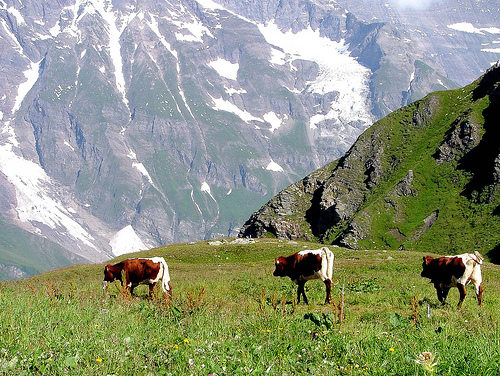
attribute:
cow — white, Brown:
[271, 241, 335, 302]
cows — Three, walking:
[84, 226, 484, 330]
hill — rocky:
[313, 121, 477, 231]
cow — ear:
[96, 243, 190, 303]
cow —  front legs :
[287, 281, 318, 309]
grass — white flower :
[96, 319, 374, 366]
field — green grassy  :
[30, 312, 302, 372]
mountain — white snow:
[6, 2, 442, 202]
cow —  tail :
[83, 250, 185, 315]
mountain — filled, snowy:
[12, 5, 403, 196]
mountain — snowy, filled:
[105, 32, 348, 160]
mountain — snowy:
[118, 8, 417, 141]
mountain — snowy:
[146, 76, 346, 194]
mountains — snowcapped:
[166, 40, 326, 168]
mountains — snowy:
[257, 14, 376, 112]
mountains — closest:
[305, 76, 496, 262]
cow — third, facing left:
[403, 242, 493, 324]